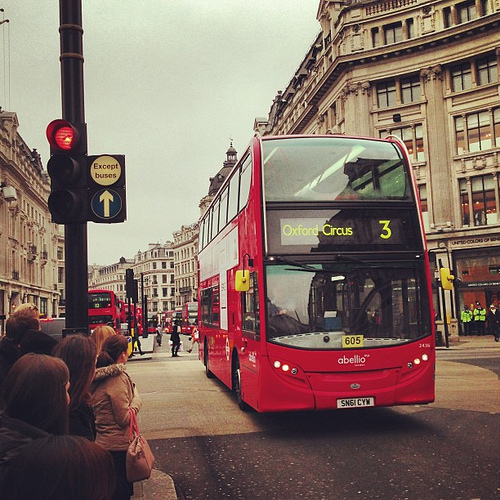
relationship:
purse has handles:
[116, 431, 163, 489] [120, 395, 150, 437]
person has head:
[85, 333, 154, 498] [89, 330, 134, 374]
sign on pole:
[85, 153, 126, 225] [56, 2, 97, 350]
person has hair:
[85, 327, 154, 498] [95, 334, 131, 366]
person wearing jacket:
[85, 333, 154, 498] [86, 362, 144, 450]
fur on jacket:
[91, 357, 126, 384] [86, 362, 144, 450]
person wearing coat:
[85, 333, 154, 498] [85, 359, 145, 457]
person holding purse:
[85, 327, 154, 498] [125, 406, 155, 481]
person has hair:
[0, 350, 117, 499] [0, 350, 70, 429]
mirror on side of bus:
[232, 265, 252, 292] [194, 131, 443, 420]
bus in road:
[194, 131, 443, 420] [115, 322, 496, 498]